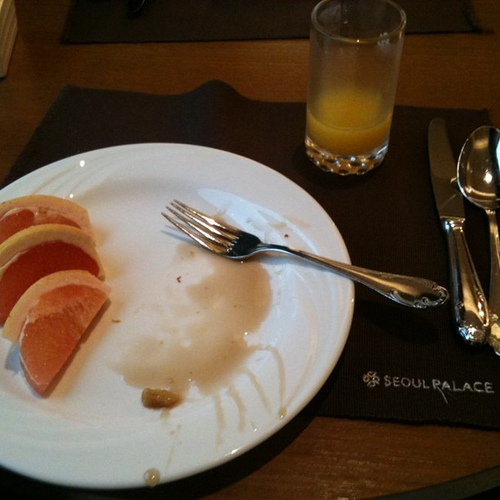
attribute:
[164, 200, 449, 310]
fork — silver, pronged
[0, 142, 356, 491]
plate — white, dirty, ceramic, shiny, round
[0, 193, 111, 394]
grapefruit — uneaten, sliced, pink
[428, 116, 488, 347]
knife — silver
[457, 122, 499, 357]
spoon — silver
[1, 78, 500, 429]
placemat — brown, black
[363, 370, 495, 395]
insignia — stitched, white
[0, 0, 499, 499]
table — wooden, light brown, brown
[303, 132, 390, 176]
bottom — thick